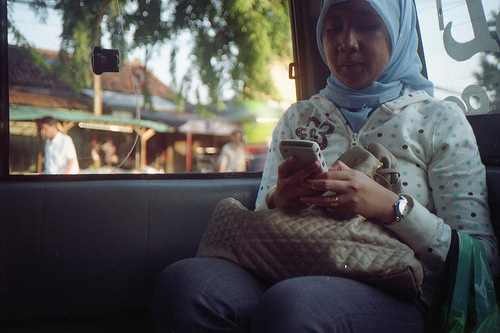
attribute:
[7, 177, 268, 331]
interior — grey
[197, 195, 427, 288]
purse — tan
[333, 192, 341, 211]
ring — gold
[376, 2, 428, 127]
scarf — blue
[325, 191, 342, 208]
ring — gold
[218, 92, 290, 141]
umbrella — blurry, green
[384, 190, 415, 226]
watch — silver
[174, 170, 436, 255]
purse — grey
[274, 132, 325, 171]
cell — white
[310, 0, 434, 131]
burka — blue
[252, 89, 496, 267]
sweater — polka dotted